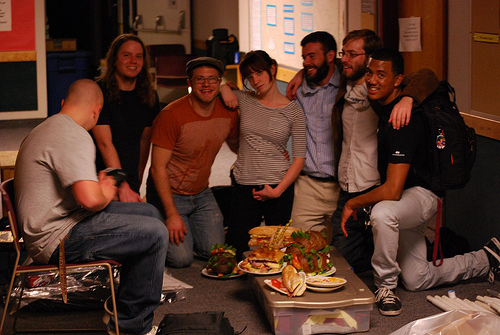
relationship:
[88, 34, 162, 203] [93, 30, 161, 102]
people has hair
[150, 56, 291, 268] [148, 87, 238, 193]
man wearing shirt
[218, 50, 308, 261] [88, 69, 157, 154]
people wearing shirt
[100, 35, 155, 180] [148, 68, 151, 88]
woman with hair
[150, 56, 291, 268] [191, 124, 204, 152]
man wearing shirt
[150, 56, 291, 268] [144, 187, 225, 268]
man wearing blue jeans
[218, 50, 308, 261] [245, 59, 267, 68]
people with hair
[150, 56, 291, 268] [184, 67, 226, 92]
man wearing glasses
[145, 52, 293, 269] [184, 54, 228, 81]
man wearing hat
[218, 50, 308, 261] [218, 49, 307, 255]
people wearing shirt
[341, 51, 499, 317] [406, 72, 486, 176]
man wearing backpack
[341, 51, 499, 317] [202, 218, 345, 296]
man enjoying meal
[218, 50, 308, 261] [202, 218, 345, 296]
people enjoying meal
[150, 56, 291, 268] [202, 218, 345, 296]
man enjoying meal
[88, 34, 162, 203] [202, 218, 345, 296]
people enjoying meal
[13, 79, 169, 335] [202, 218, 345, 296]
people enjoying meal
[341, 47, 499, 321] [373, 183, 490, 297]
man wearing light jeans